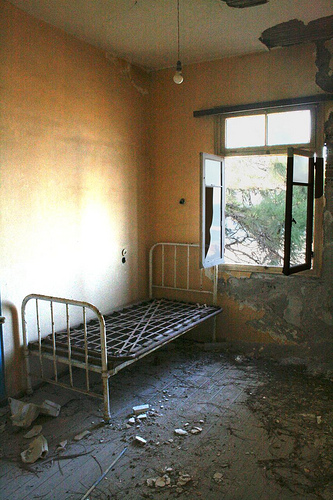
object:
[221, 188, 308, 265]
tree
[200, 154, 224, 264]
broken window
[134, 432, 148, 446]
broken plaster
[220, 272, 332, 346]
broken drywall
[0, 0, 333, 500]
room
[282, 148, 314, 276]
window door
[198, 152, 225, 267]
window door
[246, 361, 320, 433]
dirt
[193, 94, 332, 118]
curtain rod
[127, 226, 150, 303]
shadow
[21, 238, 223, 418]
bed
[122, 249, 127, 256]
outlet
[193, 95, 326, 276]
window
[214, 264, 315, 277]
window sill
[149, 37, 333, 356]
wall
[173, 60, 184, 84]
bulb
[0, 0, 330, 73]
ceiling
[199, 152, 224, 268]
wood frame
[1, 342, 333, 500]
ground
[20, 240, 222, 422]
bed frame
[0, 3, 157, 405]
wall